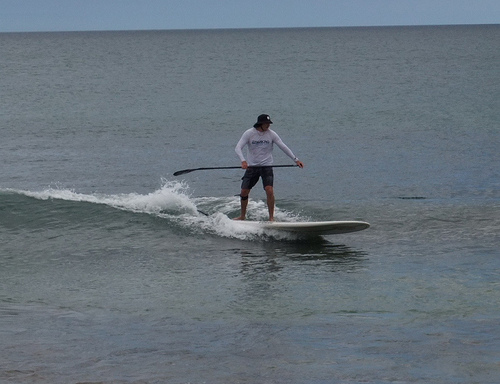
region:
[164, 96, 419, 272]
a person paddleboarding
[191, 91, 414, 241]
a paddleboarder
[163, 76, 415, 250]
a person riding on top of the water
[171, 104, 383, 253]
person in a white shirt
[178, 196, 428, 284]
a paddleboard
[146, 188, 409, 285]
a white paddleboard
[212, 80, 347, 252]
a man in black shorts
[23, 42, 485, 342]
man in the middle of the water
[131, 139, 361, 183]
a black oar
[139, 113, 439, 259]
man carrying an oar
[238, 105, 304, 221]
a man wearing a hat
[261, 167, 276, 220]
a man's leg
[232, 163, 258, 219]
a man's leg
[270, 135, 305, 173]
a man's hand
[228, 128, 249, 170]
a man's hand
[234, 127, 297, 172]
a white sweater worn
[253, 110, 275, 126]
a black hat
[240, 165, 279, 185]
black shorts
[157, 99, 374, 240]
a man surfing in water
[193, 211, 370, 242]
a surfing board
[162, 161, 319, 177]
black paddle in the air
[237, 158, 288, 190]
dark colored swim shorts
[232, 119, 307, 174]
long sleeve white swim top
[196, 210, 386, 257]
white and large board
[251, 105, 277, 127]
dark colored baseball cap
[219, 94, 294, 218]
man standing on the white board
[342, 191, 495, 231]
small wave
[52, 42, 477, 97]
open water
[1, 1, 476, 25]
clear and blue skies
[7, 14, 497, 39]
the horizon's behind the man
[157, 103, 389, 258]
Surfer holding a paddle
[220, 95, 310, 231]
Man standing on a surfboard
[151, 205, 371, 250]
Surfboard is big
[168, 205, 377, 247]
Surfboard is white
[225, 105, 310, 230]
Person wearing long sleeve shirt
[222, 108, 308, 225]
Person wearing white shirt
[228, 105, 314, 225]
Man wearing black short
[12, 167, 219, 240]
Choppy water formed by the surfboard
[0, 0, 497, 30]
Sky is dark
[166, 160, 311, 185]
Black paddle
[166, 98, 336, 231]
The person is standing up.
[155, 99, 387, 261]
The man rides a surfboard.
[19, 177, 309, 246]
The surfboard rides a wave.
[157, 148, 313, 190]
The man holds a paddle.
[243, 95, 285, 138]
The man wears a black cap.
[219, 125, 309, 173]
The man wears a white top.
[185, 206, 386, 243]
The surfboard is white.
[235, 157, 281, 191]
The man is wearing shorts.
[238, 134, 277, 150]
A word is visible on the man's shirt.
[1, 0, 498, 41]
The sky is blue.